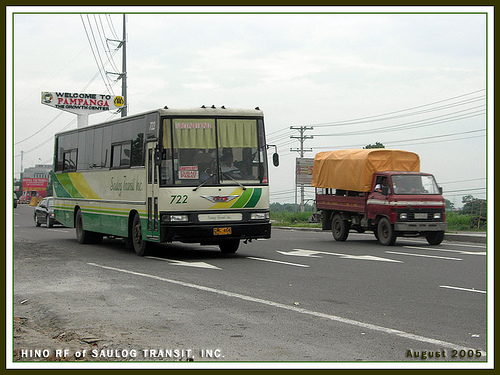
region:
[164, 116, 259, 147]
the shade on the windshield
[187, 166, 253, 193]
the wipers on the window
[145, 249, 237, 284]
the white arrow on the ground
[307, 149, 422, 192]
the prange canopy over the bed of the truck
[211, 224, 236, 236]
the plate on the front of the bus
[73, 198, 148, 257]
the tires on the bus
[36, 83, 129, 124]
the white sign above the bus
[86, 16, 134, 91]
the post for the power lines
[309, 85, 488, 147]
the power lines hanging in the air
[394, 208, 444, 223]
the headlights on the front of the truck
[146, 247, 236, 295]
arrow lines on pavement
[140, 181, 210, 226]
the number is 722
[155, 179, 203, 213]
the number is 722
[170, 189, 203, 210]
the number is 722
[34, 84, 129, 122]
White sign for store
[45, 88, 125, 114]
Black and red writing on sign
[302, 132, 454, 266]
Brown truck on the road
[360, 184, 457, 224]
White stripe on front of truck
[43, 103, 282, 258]
Green yellow and white bus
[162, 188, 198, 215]
Green number 722 on front of bus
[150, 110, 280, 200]
Large window on front of bus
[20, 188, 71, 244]
small black car behind bus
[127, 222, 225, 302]
White arrow on road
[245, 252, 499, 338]
White lines in the road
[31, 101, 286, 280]
a bus on the road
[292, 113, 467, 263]
the truck is red with tarp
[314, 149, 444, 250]
a red and orange truck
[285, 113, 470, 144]
the electrical wiring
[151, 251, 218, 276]
a white arrow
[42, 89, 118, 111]
it says welcome to PAMPANGA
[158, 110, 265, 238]
the front view of the bus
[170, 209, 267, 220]
the headlights of the bus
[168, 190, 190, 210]
the number 722 in green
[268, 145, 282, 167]
the rearview mirror of the bus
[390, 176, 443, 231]
the front view of the truck